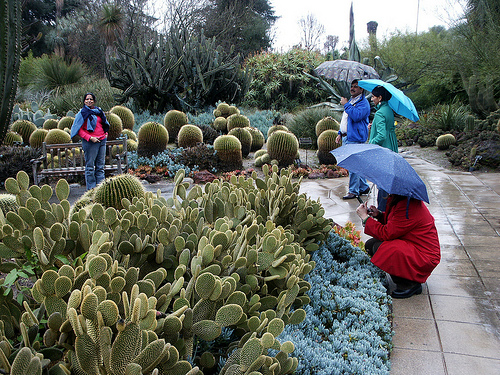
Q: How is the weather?
A: It is cloudy.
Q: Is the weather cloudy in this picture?
A: Yes, it is cloudy.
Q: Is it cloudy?
A: Yes, it is cloudy.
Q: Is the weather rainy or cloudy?
A: It is cloudy.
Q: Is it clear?
A: No, it is cloudy.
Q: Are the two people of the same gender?
A: No, they are both male and female.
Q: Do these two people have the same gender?
A: No, they are both male and female.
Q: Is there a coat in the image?
A: Yes, there is a coat.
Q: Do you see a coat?
A: Yes, there is a coat.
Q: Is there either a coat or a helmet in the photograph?
A: Yes, there is a coat.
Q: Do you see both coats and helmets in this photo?
A: No, there is a coat but no helmets.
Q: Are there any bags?
A: No, there are no bags.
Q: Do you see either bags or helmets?
A: No, there are no bags or helmets.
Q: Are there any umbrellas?
A: Yes, there is an umbrella.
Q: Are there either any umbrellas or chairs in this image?
A: Yes, there is an umbrella.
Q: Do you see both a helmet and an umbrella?
A: No, there is an umbrella but no helmets.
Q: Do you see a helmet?
A: No, there are no helmets.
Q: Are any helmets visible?
A: No, there are no helmets.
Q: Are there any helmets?
A: No, there are no helmets.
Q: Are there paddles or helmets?
A: No, there are no helmets or paddles.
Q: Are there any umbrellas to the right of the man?
A: Yes, there is an umbrella to the right of the man.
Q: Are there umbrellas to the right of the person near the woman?
A: Yes, there is an umbrella to the right of the man.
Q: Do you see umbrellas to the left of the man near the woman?
A: No, the umbrella is to the right of the man.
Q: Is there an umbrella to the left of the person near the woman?
A: No, the umbrella is to the right of the man.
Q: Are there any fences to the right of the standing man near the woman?
A: No, there is an umbrella to the right of the man.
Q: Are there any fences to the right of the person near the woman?
A: No, there is an umbrella to the right of the man.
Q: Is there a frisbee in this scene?
A: No, there are no frisbees.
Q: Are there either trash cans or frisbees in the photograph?
A: No, there are no frisbees or trash cans.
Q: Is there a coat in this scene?
A: Yes, there is a coat.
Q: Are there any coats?
A: Yes, there is a coat.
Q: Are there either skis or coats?
A: Yes, there is a coat.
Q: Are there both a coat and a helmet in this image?
A: No, there is a coat but no helmets.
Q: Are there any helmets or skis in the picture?
A: No, there are no helmets or skis.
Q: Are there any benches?
A: Yes, there is a bench.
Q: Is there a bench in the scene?
A: Yes, there is a bench.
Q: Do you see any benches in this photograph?
A: Yes, there is a bench.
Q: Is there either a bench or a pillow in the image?
A: Yes, there is a bench.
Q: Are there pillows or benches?
A: Yes, there is a bench.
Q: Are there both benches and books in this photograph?
A: No, there is a bench but no books.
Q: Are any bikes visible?
A: No, there are no bikes.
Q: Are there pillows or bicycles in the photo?
A: No, there are no bicycles or pillows.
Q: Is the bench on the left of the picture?
A: Yes, the bench is on the left of the image.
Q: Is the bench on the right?
A: No, the bench is on the left of the image.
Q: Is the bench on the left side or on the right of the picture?
A: The bench is on the left of the image.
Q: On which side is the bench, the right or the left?
A: The bench is on the left of the image.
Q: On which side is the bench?
A: The bench is on the left of the image.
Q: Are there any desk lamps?
A: No, there are no desk lamps.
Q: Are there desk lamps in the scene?
A: No, there are no desk lamps.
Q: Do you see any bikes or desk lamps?
A: No, there are no desk lamps or bikes.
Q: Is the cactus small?
A: Yes, the cactus is small.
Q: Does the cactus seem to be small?
A: Yes, the cactus is small.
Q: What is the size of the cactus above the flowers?
A: The cactus is small.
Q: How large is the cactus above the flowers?
A: The cactus is small.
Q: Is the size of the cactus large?
A: No, the cactus is small.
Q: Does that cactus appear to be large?
A: No, the cactus is small.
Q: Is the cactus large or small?
A: The cactus is small.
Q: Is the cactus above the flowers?
A: Yes, the cactus is above the flowers.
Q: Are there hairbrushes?
A: No, there are no hairbrushes.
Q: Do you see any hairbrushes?
A: No, there are no hairbrushes.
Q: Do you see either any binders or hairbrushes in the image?
A: No, there are no hairbrushes or binders.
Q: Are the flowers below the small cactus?
A: Yes, the flowers are below the cactus.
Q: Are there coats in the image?
A: Yes, there is a coat.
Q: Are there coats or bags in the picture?
A: Yes, there is a coat.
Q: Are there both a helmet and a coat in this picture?
A: No, there is a coat but no helmets.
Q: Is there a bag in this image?
A: No, there are no bags.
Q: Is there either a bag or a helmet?
A: No, there are no bags or helmets.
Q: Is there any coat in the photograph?
A: Yes, there is a coat.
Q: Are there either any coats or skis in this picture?
A: Yes, there is a coat.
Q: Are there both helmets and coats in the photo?
A: No, there is a coat but no helmets.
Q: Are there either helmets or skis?
A: No, there are no helmets or skis.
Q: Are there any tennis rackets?
A: No, there are no tennis rackets.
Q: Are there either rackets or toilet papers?
A: No, there are no rackets or toilet papers.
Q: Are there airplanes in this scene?
A: No, there are no airplanes.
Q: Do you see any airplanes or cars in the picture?
A: No, there are no airplanes or cars.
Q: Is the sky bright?
A: Yes, the sky is bright.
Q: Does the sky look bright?
A: Yes, the sky is bright.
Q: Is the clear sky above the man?
A: Yes, the sky is above the man.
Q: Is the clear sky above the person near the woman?
A: Yes, the sky is above the man.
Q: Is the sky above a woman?
A: Yes, the sky is above a woman.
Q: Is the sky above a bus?
A: No, the sky is above a woman.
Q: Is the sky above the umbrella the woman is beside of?
A: Yes, the sky is above the umbrella.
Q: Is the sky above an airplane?
A: No, the sky is above the umbrella.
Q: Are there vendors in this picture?
A: No, there are no vendors.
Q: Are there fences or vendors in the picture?
A: No, there are no vendors or fences.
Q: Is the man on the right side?
A: Yes, the man is on the right of the image.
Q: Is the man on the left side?
A: No, the man is on the right of the image.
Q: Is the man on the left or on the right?
A: The man is on the right of the image.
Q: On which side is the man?
A: The man is on the right of the image.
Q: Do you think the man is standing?
A: Yes, the man is standing.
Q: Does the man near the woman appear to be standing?
A: Yes, the man is standing.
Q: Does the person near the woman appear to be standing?
A: Yes, the man is standing.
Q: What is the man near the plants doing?
A: The man is standing.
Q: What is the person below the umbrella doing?
A: The man is standing.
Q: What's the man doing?
A: The man is standing.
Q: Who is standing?
A: The man is standing.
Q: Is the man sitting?
A: No, the man is standing.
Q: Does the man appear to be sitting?
A: No, the man is standing.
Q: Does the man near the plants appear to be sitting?
A: No, the man is standing.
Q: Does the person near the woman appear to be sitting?
A: No, the man is standing.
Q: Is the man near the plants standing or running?
A: The man is standing.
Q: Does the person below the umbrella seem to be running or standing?
A: The man is standing.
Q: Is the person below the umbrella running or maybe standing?
A: The man is standing.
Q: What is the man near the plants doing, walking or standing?
A: The man is standing.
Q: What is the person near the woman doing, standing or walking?
A: The man is standing.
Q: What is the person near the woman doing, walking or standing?
A: The man is standing.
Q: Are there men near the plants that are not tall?
A: Yes, there is a man near the plants.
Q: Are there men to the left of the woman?
A: Yes, there is a man to the left of the woman.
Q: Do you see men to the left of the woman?
A: Yes, there is a man to the left of the woman.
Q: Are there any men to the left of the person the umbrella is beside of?
A: Yes, there is a man to the left of the woman.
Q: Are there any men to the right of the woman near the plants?
A: No, the man is to the left of the woman.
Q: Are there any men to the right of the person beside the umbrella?
A: No, the man is to the left of the woman.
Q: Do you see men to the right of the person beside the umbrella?
A: No, the man is to the left of the woman.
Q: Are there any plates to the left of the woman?
A: No, there is a man to the left of the woman.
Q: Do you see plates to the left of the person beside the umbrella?
A: No, there is a man to the left of the woman.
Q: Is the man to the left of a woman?
A: Yes, the man is to the left of a woman.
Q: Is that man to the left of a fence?
A: No, the man is to the left of a woman.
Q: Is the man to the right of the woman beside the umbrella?
A: No, the man is to the left of the woman.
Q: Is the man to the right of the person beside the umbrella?
A: No, the man is to the left of the woman.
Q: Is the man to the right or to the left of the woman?
A: The man is to the left of the woman.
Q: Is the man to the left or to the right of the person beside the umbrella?
A: The man is to the left of the woman.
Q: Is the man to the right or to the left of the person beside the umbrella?
A: The man is to the left of the woman.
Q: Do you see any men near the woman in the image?
A: Yes, there is a man near the woman.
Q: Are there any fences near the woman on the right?
A: No, there is a man near the woman.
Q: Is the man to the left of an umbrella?
A: Yes, the man is to the left of an umbrella.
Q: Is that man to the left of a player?
A: No, the man is to the left of an umbrella.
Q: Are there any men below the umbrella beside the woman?
A: Yes, there is a man below the umbrella.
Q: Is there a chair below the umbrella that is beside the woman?
A: No, there is a man below the umbrella.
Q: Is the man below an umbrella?
A: Yes, the man is below an umbrella.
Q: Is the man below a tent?
A: No, the man is below an umbrella.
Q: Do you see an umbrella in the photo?
A: Yes, there is an umbrella.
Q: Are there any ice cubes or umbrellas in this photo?
A: Yes, there is an umbrella.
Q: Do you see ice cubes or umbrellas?
A: Yes, there is an umbrella.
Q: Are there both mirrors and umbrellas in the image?
A: No, there is an umbrella but no mirrors.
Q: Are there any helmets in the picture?
A: No, there are no helmets.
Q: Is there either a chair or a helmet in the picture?
A: No, there are no helmets or chairs.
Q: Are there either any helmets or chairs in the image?
A: No, there are no helmets or chairs.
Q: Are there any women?
A: Yes, there is a woman.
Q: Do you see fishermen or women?
A: Yes, there is a woman.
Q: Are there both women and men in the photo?
A: Yes, there are both a woman and a man.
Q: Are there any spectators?
A: No, there are no spectators.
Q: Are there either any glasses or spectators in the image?
A: No, there are no spectators or glasses.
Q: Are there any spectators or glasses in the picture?
A: No, there are no spectators or glasses.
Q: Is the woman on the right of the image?
A: Yes, the woman is on the right of the image.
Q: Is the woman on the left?
A: No, the woman is on the right of the image.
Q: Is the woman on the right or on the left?
A: The woman is on the right of the image.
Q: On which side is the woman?
A: The woman is on the right of the image.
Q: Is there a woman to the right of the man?
A: Yes, there is a woman to the right of the man.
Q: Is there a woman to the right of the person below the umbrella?
A: Yes, there is a woman to the right of the man.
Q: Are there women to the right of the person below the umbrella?
A: Yes, there is a woman to the right of the man.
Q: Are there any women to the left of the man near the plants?
A: No, the woman is to the right of the man.